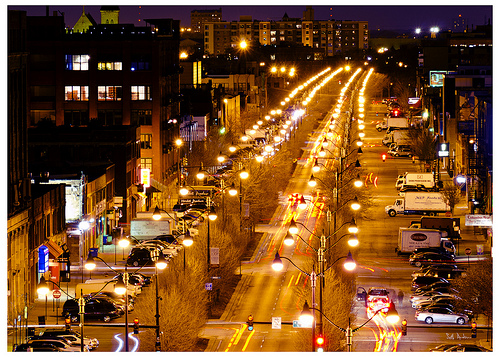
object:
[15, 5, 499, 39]
sky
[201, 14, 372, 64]
building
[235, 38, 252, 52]
lights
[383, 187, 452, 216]
truck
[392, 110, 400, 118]
light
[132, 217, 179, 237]
sign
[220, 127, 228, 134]
light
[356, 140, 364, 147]
light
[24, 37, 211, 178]
buildings